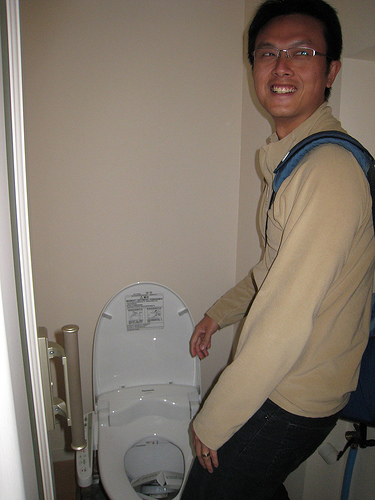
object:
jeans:
[178, 398, 337, 499]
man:
[174, 1, 375, 500]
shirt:
[193, 101, 375, 451]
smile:
[269, 80, 299, 98]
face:
[254, 15, 326, 118]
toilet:
[87, 283, 206, 492]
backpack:
[264, 130, 375, 432]